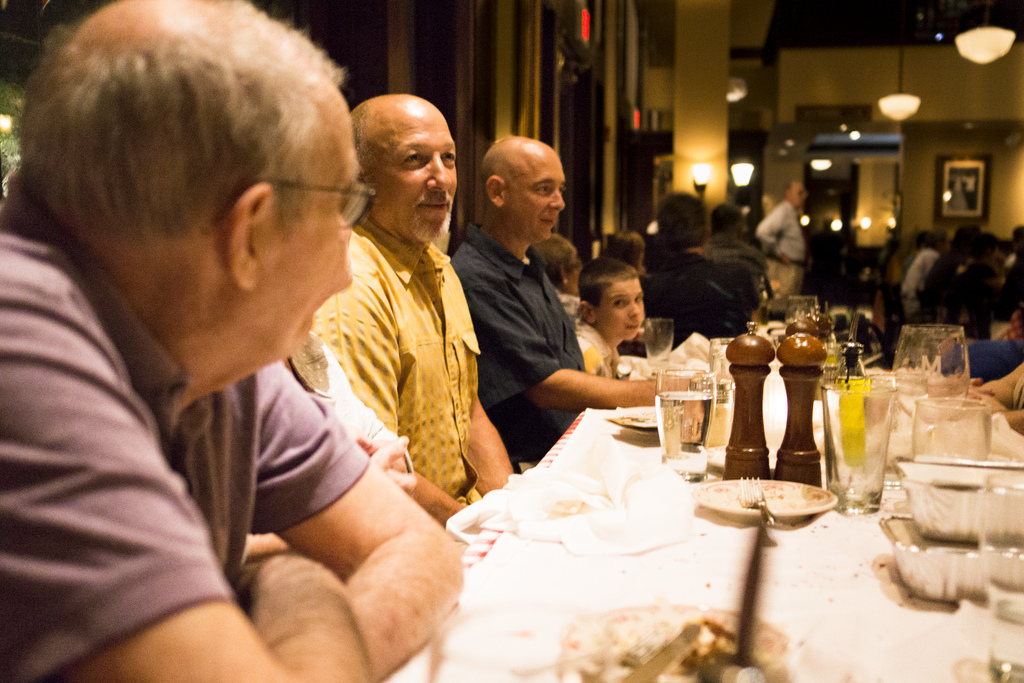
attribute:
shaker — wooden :
[717, 320, 782, 488]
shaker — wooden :
[773, 320, 830, 488]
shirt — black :
[461, 228, 604, 393]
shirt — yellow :
[324, 222, 480, 438]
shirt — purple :
[25, 313, 321, 626]